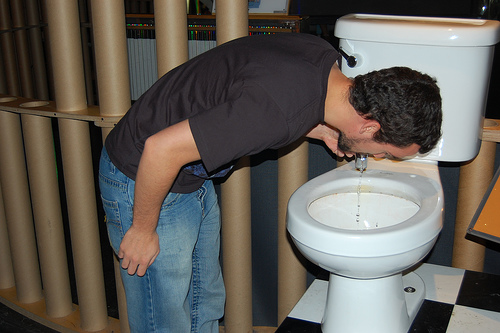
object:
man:
[92, 30, 444, 332]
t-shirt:
[103, 31, 342, 194]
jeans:
[97, 142, 232, 331]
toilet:
[284, 10, 499, 331]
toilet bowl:
[282, 162, 446, 258]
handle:
[335, 43, 360, 69]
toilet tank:
[328, 10, 498, 163]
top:
[333, 11, 499, 48]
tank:
[333, 10, 500, 163]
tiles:
[450, 267, 499, 313]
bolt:
[403, 285, 417, 294]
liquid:
[346, 150, 374, 231]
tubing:
[57, 115, 106, 333]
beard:
[336, 128, 376, 157]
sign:
[465, 164, 500, 248]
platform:
[273, 254, 500, 331]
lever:
[334, 40, 361, 71]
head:
[336, 64, 445, 161]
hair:
[348, 66, 444, 153]